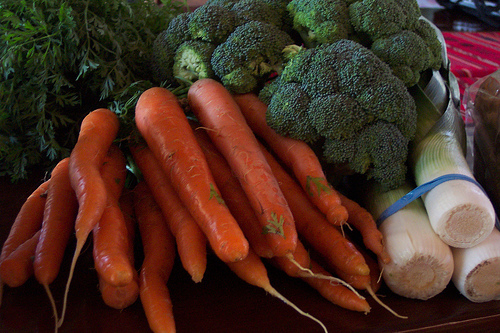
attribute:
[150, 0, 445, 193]
broccoli — green, fresh, piled, dark green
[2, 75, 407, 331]
carrots — bunched, fresh, orange, piled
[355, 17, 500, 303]
leeks — green, white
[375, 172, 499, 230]
rubberband — blue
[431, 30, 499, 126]
cloth — multi colored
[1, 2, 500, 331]
table — wooden